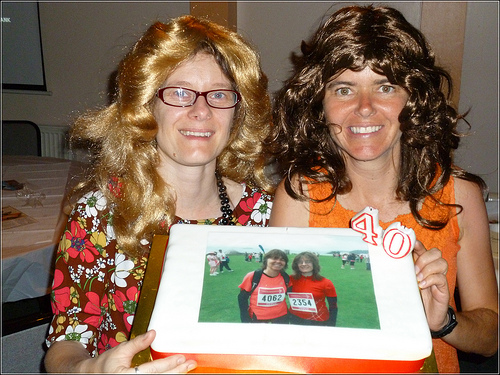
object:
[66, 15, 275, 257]
blonde hair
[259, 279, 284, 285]
red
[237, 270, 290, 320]
shirt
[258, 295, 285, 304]
number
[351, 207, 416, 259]
40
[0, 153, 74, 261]
table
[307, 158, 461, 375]
dress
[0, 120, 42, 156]
chair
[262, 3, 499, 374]
girl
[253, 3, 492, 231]
hair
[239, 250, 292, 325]
woman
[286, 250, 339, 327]
woman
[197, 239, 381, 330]
picture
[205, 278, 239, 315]
grass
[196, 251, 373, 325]
field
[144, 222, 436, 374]
cake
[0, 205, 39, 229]
items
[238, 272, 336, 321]
red tops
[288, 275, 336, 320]
shirt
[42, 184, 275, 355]
dress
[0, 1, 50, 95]
board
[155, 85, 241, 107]
glasses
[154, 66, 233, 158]
face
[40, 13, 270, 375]
woman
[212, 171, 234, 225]
necklace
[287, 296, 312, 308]
numbers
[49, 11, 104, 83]
wall